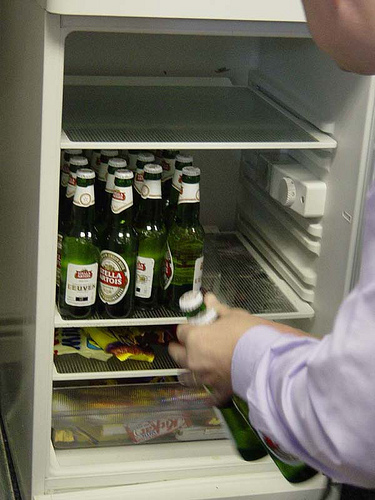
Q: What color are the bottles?
A: Green.